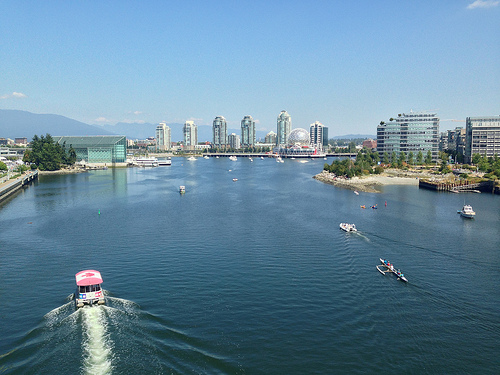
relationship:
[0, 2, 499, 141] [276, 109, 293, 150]
sky above building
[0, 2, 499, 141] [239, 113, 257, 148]
sky above building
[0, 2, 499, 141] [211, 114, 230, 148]
sky above building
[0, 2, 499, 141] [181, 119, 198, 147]
sky above building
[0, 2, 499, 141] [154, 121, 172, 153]
sky above building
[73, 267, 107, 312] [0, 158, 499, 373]
boat in water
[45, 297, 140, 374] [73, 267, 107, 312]
water behind boat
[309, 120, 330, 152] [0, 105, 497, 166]
building in background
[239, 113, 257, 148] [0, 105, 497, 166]
building in background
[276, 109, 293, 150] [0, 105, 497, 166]
building in background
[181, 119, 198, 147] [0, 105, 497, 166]
building in background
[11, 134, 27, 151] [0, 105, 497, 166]
building in background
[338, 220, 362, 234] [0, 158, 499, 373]
boat in water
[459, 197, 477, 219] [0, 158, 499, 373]
boat in water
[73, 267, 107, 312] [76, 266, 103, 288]
boat has roof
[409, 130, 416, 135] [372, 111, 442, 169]
window in building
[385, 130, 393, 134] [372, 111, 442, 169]
window in building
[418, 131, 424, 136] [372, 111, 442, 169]
window in building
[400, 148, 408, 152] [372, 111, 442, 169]
window in building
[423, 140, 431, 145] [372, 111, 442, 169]
window in building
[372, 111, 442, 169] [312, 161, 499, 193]
building next to shore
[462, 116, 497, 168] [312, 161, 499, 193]
building next to shore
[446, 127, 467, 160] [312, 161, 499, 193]
building next to shore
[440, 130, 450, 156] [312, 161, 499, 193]
building next to shore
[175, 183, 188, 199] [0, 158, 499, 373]
boat in water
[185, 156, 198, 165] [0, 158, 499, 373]
boat in water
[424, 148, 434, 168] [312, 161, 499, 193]
tree on shore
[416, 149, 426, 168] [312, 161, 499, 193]
tree on shore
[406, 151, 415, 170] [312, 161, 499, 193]
tree on shore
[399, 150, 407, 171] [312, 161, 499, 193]
tree on shore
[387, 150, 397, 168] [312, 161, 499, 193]
tree on shore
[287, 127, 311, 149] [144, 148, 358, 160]
building on shore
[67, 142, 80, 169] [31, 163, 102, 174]
tree on land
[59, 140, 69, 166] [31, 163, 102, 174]
tree on land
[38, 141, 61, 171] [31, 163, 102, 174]
tree on land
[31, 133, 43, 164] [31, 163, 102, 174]
tree on land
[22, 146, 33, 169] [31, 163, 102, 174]
tree on land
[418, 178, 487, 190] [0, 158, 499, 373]
deck protrudes into water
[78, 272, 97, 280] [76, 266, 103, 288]
symbol on roof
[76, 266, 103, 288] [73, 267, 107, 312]
roof on boat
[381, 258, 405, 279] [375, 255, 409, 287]
people are sitting in row boat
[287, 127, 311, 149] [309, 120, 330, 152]
building near building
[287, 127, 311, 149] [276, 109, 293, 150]
building near building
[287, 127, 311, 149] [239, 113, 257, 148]
building near building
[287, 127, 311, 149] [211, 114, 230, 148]
building near building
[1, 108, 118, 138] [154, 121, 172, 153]
mountain left of building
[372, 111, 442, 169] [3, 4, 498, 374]
building right of image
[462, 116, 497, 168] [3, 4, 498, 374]
building right of image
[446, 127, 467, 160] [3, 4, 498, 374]
building right of image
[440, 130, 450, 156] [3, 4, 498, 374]
building right of image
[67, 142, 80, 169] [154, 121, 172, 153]
tree left of building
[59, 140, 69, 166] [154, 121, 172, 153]
tree left of building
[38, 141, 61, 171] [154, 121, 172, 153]
tree left of building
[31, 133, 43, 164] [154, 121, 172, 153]
tree left of building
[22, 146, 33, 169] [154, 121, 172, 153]
tree left of building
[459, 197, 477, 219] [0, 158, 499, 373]
boat in right of water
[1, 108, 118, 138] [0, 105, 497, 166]
mountain in background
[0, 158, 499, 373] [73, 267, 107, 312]
water under boat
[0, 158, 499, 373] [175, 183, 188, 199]
water under boat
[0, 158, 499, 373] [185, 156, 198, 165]
water under boat